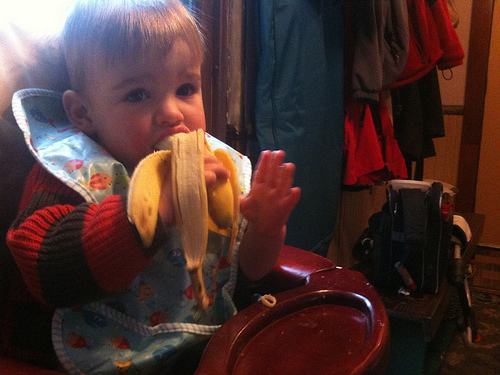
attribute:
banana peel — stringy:
[129, 131, 241, 311]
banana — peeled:
[123, 128, 240, 307]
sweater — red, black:
[45, 145, 97, 234]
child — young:
[30, 22, 279, 357]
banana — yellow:
[150, 120, 237, 270]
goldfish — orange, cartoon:
[81, 172, 115, 192]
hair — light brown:
[62, 2, 199, 64]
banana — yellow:
[116, 125, 246, 314]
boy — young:
[4, 1, 310, 373]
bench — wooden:
[361, 177, 487, 369]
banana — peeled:
[147, 149, 260, 253]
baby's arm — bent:
[8, 155, 233, 309]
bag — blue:
[252, 2, 351, 262]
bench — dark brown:
[388, 296, 460, 337]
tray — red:
[202, 284, 387, 372]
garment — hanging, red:
[347, 84, 413, 177]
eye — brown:
[176, 81, 198, 97]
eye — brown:
[121, 86, 155, 103]